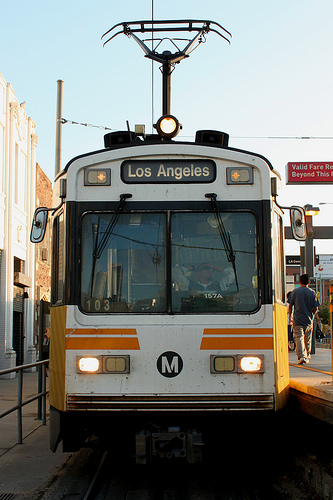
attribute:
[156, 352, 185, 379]
letter — m, black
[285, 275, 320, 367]
man — walking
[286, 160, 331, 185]
sign — red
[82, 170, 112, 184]
light — on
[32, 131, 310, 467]
train — orange, positioned, headed, white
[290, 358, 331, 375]
stripe — yellow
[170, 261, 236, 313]
driver — leaning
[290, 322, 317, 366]
pants — brown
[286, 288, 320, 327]
shirt — blue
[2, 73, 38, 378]
building — white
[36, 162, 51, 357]
building — brown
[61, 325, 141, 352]
stripe — orange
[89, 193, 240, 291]
wipers — black